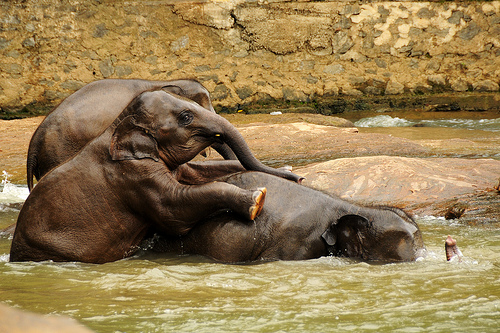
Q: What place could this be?
A: It is a river.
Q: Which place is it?
A: It is a river.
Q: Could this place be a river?
A: Yes, it is a river.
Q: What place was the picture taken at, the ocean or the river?
A: It was taken at the river.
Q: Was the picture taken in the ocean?
A: No, the picture was taken in the river.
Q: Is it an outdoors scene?
A: Yes, it is outdoors.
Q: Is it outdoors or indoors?
A: It is outdoors.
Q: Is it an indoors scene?
A: No, it is outdoors.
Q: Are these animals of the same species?
A: Yes, all the animals are elephants.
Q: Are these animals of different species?
A: No, all the animals are elephants.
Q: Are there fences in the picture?
A: No, there are no fences.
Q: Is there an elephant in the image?
A: Yes, there is an elephant.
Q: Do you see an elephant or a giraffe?
A: Yes, there is an elephant.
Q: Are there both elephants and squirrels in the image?
A: No, there is an elephant but no squirrels.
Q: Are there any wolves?
A: No, there are no wolves.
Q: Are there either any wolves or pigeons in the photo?
A: No, there are no wolves or pigeons.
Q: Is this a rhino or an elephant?
A: This is an elephant.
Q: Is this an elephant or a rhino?
A: This is an elephant.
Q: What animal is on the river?
A: The elephant is on the river.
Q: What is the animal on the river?
A: The animal is an elephant.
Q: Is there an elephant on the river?
A: Yes, there is an elephant on the river.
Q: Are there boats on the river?
A: No, there is an elephant on the river.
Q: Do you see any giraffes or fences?
A: No, there are no fences or giraffes.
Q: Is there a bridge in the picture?
A: No, there are no bridges.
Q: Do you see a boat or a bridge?
A: No, there are no bridges or boats.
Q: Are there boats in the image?
A: No, there are no boats.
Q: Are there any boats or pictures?
A: No, there are no boats or pictures.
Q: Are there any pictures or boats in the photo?
A: No, there are no boats or pictures.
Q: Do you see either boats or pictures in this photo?
A: No, there are no boats or pictures.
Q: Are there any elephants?
A: Yes, there are elephants.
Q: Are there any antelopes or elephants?
A: Yes, there are elephants.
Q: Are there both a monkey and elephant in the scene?
A: No, there are elephants but no monkeys.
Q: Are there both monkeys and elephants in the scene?
A: No, there are elephants but no monkeys.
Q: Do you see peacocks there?
A: No, there are no peacocks.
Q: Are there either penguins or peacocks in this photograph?
A: No, there are no peacocks or penguins.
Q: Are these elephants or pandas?
A: These are elephants.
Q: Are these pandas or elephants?
A: These are elephants.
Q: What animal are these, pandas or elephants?
A: These are elephants.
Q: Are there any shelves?
A: No, there are no shelves.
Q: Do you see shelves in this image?
A: No, there are no shelves.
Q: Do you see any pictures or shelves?
A: No, there are no shelves or pictures.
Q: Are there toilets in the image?
A: No, there are no toilets.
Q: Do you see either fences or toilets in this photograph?
A: No, there are no toilets or fences.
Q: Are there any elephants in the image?
A: Yes, there is an elephant.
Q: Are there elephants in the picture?
A: Yes, there is an elephant.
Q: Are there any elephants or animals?
A: Yes, there is an elephant.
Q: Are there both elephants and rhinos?
A: No, there is an elephant but no rhinos.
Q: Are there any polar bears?
A: No, there are no polar bears.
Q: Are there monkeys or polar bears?
A: No, there are no polar bears or monkeys.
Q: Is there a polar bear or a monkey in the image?
A: No, there are no polar bears or monkeys.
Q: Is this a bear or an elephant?
A: This is an elephant.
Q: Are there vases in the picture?
A: No, there are no vases.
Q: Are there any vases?
A: No, there are no vases.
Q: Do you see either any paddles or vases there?
A: No, there are no vases or paddles.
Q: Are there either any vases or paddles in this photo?
A: No, there are no vases or paddles.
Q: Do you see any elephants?
A: Yes, there is an elephant.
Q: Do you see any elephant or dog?
A: Yes, there is an elephant.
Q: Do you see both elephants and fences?
A: No, there is an elephant but no fences.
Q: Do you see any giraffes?
A: No, there are no giraffes.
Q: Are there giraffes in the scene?
A: No, there are no giraffes.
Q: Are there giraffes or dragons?
A: No, there are no giraffes or dragons.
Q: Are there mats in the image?
A: No, there are no mats.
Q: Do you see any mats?
A: No, there are no mats.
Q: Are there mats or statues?
A: No, there are no mats or statues.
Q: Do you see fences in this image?
A: No, there are no fences.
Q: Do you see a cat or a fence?
A: No, there are no fences or cats.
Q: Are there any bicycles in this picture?
A: No, there are no bicycles.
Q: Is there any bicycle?
A: No, there are no bicycles.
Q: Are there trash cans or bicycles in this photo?
A: No, there are no bicycles or trash cans.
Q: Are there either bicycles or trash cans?
A: No, there are no bicycles or trash cans.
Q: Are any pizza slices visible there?
A: No, there are no pizza slices.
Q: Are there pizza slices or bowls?
A: No, there are no pizza slices or bowls.